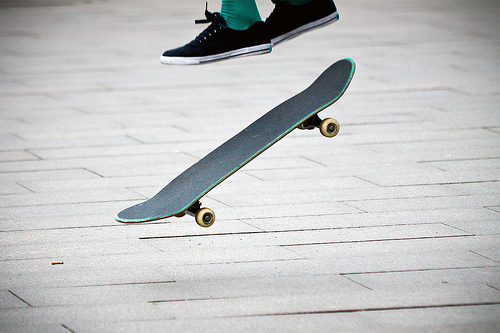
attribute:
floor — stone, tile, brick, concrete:
[1, 3, 499, 332]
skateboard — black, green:
[114, 58, 354, 225]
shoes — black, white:
[161, 3, 337, 65]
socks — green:
[219, 0, 263, 30]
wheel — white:
[195, 208, 212, 226]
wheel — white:
[175, 210, 185, 217]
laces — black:
[194, 4, 223, 28]